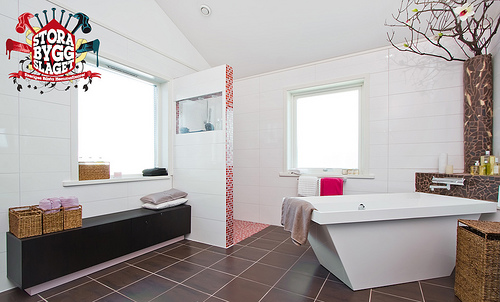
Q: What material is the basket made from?
A: Wicker.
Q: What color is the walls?
A: White.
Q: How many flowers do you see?
A: 1.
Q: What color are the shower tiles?
A: Red.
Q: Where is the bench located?
A: Under left window.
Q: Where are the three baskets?
A: Left side of bench.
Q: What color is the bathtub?
A: White.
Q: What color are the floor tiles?
A: Brown.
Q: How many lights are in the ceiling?
A: 1.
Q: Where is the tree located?
A: Top Right.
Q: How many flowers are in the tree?
A: 1.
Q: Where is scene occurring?
A: A bathroom.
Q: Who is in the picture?
A: No one.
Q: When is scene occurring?
A: Daytime.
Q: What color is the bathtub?
A: White.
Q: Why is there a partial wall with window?
A: To create shower.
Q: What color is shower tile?
A: Red.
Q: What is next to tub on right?
A: Wicker basket with top.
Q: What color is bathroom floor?
A: Brown.